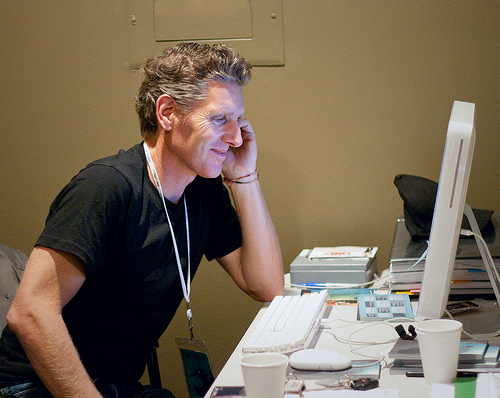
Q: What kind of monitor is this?
A: Computer monitor.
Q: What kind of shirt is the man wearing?
A: Black shirt.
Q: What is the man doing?
A: Smiling.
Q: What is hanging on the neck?
A: White lanyard.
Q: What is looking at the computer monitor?
A: The man.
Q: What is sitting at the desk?
A: The man.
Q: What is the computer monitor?
A: White.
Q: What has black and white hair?
A: The man.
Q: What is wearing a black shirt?
A: The man.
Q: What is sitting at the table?
A: The man.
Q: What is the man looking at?
A: Computer screen.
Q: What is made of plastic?
A: Cups.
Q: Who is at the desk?
A: A man.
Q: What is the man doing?
A: Looking at the computer.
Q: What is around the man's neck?
A: An ID badge.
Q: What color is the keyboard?
A: White.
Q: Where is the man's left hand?
A: By his face.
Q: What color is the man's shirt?
A: Black.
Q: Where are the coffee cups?
A: On the desk.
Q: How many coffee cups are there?
A: Two.